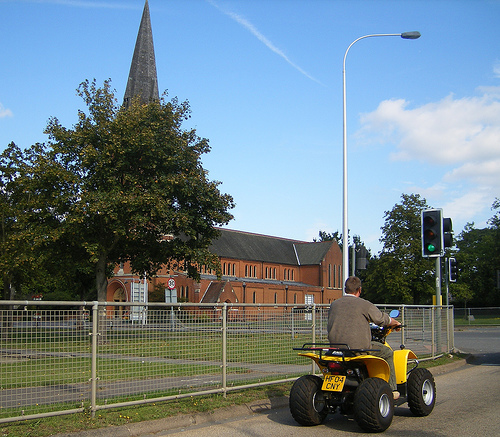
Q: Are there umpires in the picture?
A: No, there are no umpires.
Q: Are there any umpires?
A: No, there are no umpires.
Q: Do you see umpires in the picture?
A: No, there are no umpires.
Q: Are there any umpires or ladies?
A: No, there are no umpires or ladies.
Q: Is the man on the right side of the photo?
A: Yes, the man is on the right of the image.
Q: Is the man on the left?
A: No, the man is on the right of the image.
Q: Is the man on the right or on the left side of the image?
A: The man is on the right of the image.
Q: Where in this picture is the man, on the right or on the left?
A: The man is on the right of the image.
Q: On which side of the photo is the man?
A: The man is on the right of the image.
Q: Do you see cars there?
A: No, there are no cars.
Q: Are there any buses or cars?
A: No, there are no cars or buses.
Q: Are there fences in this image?
A: Yes, there is a fence.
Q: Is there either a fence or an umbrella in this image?
A: Yes, there is a fence.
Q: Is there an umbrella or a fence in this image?
A: Yes, there is a fence.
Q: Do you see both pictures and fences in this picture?
A: No, there is a fence but no pictures.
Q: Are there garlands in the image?
A: No, there are no garlands.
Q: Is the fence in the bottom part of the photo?
A: Yes, the fence is in the bottom of the image.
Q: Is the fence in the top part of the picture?
A: No, the fence is in the bottom of the image.